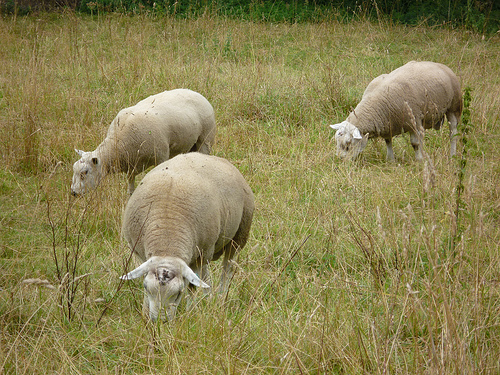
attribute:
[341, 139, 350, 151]
eye — black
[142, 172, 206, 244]
fleece — beige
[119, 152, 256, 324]
sheep — standing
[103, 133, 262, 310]
sheep — standing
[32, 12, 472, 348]
pasture — grassy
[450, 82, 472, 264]
plant — single, green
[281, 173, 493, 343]
grass — green, brown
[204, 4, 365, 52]
trees — growing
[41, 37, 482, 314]
sheeps — big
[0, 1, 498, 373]
grass — food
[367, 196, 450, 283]
grass — green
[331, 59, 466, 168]
sheep — sheared